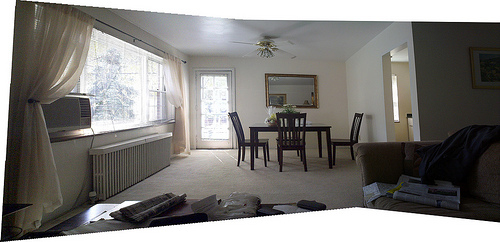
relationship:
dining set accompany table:
[228, 111, 364, 172] [249, 125, 333, 170]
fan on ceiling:
[230, 36, 295, 62] [108, 8, 394, 62]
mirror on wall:
[265, 73, 319, 108] [188, 55, 351, 149]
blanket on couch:
[416, 125, 500, 185] [353, 141, 500, 222]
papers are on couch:
[362, 174, 461, 211] [353, 141, 500, 222]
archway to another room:
[379, 21, 415, 59] [391, 48, 415, 142]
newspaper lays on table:
[110, 188, 187, 223] [43, 201, 316, 237]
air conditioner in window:
[41, 92, 91, 133] [34, 3, 175, 143]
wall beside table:
[188, 55, 351, 149] [249, 125, 333, 170]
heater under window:
[88, 132, 172, 205] [34, 3, 175, 143]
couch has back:
[353, 141, 500, 222] [464, 143, 500, 205]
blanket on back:
[416, 125, 500, 185] [464, 143, 500, 205]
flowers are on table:
[282, 105, 296, 126] [249, 125, 333, 170]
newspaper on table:
[110, 188, 187, 223] [43, 201, 316, 237]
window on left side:
[34, 3, 175, 143] [0, 0, 274, 241]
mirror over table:
[265, 73, 319, 108] [249, 125, 333, 170]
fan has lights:
[230, 36, 295, 62] [258, 49, 276, 58]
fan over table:
[230, 36, 295, 62] [249, 125, 333, 170]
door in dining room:
[196, 71, 233, 149] [145, 21, 420, 174]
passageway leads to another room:
[382, 42, 414, 142] [391, 48, 415, 142]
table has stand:
[249, 125, 333, 170] [327, 130, 333, 168]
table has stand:
[249, 125, 333, 170] [317, 131, 322, 157]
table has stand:
[249, 125, 333, 170] [251, 132, 255, 169]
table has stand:
[249, 125, 333, 170] [255, 132, 259, 158]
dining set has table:
[228, 111, 364, 172] [249, 125, 333, 170]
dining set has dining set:
[228, 111, 364, 172] [228, 111, 364, 172]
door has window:
[196, 71, 233, 149] [201, 76, 230, 138]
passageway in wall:
[382, 42, 414, 142] [345, 21, 421, 153]